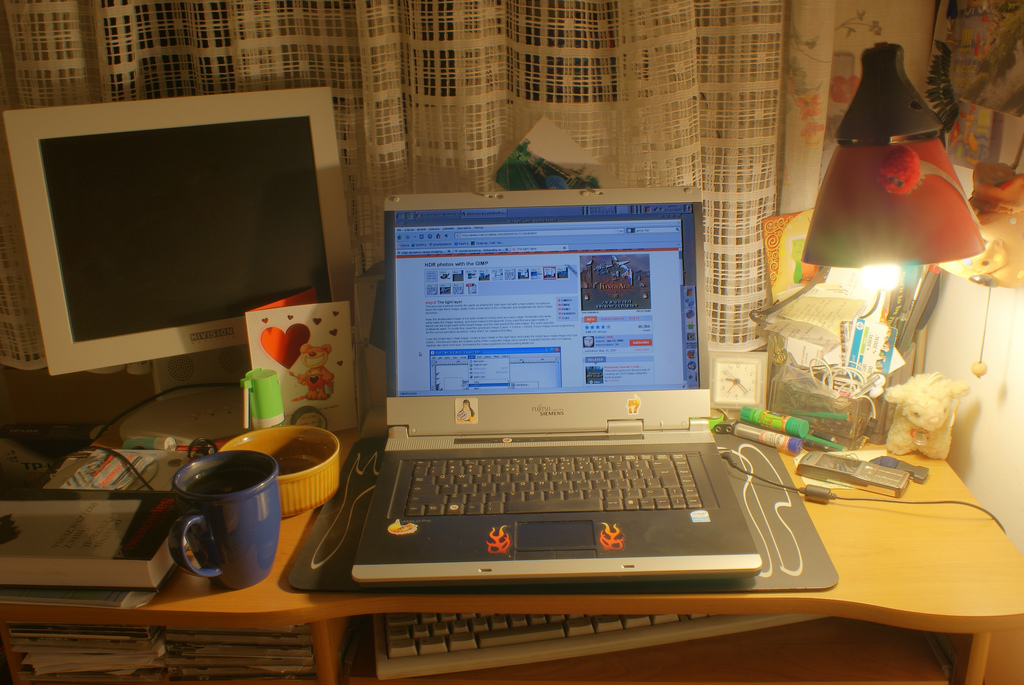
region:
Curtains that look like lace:
[1, 1, 796, 378]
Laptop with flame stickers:
[346, 182, 758, 587]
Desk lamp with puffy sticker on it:
[747, 35, 986, 315]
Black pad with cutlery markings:
[283, 428, 838, 591]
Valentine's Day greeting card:
[239, 280, 360, 439]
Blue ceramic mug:
[162, 443, 281, 590]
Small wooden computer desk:
[4, 400, 1020, 679]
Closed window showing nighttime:
[1, 2, 795, 370]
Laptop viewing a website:
[348, 184, 770, 581]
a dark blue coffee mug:
[171, 452, 277, 592]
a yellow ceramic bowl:
[217, 426, 342, 513]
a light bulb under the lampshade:
[857, 260, 908, 293]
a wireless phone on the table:
[795, 448, 909, 494]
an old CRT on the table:
[4, 83, 362, 387]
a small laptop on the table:
[342, 186, 763, 594]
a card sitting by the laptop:
[245, 297, 360, 433]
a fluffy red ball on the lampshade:
[874, 143, 919, 197]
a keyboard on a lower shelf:
[364, 604, 823, 682]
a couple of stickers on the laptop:
[484, 521, 627, 561]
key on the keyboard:
[636, 481, 674, 513]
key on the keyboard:
[656, 448, 685, 464]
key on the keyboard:
[566, 455, 598, 466]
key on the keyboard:
[418, 459, 435, 466]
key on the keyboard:
[456, 458, 475, 471]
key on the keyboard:
[528, 459, 545, 472]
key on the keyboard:
[457, 506, 468, 519]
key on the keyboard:
[529, 493, 561, 514]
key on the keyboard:
[500, 626, 549, 647]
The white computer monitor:
[1, 77, 357, 375]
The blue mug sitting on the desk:
[160, 446, 291, 601]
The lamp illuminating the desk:
[791, 34, 992, 292]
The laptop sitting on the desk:
[346, 183, 762, 589]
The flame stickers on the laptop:
[478, 516, 633, 561]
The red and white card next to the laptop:
[234, 288, 370, 419]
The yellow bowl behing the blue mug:
[226, 418, 353, 518]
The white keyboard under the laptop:
[358, 607, 842, 675]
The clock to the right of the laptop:
[709, 344, 774, 420]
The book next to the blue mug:
[2, 468, 186, 595]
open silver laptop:
[318, 175, 767, 571]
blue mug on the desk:
[158, 447, 291, 584]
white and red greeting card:
[247, 288, 352, 434]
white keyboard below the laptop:
[360, 619, 854, 680]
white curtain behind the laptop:
[13, 0, 767, 324]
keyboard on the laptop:
[399, 450, 693, 521]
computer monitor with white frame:
[16, 86, 377, 400]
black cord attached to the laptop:
[724, 442, 1001, 528]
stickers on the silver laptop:
[369, 513, 724, 577]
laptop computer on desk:
[344, 179, 766, 584]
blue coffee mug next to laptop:
[164, 445, 285, 589]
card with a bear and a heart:
[237, 281, 370, 437]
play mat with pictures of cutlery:
[277, 424, 841, 595]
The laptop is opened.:
[348, 185, 763, 585]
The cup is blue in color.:
[160, 454, 287, 594]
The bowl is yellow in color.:
[210, 422, 348, 509]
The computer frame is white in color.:
[4, 81, 359, 380]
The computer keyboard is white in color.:
[364, 618, 821, 676]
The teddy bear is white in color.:
[882, 375, 969, 464]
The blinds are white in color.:
[7, 4, 792, 358]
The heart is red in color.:
[256, 321, 315, 369]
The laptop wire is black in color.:
[727, 451, 1012, 537]